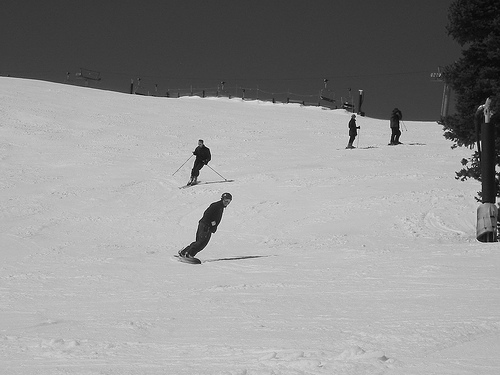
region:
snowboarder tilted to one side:
[161, 190, 244, 272]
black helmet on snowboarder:
[218, 186, 236, 207]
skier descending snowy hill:
[153, 131, 244, 196]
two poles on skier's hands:
[166, 151, 233, 183]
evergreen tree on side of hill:
[438, 94, 498, 202]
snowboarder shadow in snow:
[220, 245, 273, 265]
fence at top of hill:
[193, 79, 288, 109]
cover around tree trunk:
[470, 199, 498, 251]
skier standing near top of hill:
[338, 109, 368, 155]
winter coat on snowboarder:
[192, 197, 229, 233]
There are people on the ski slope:
[48, 23, 467, 348]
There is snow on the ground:
[23, 53, 443, 370]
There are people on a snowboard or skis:
[51, 39, 437, 374]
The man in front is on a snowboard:
[53, 21, 467, 367]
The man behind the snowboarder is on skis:
[104, 45, 413, 365]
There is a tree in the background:
[63, 1, 497, 249]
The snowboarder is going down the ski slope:
[103, 179, 426, 351]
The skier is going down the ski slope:
[90, 98, 379, 314]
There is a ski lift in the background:
[48, 41, 451, 318]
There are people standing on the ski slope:
[302, 79, 426, 219]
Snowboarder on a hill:
[163, 178, 238, 278]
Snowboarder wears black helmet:
[167, 182, 237, 268]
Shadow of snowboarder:
[208, 243, 286, 273]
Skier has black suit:
[166, 131, 241, 188]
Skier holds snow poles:
[166, 132, 236, 185]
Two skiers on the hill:
[326, 96, 416, 158]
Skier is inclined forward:
[173, 183, 245, 276]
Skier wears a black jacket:
[172, 175, 239, 281]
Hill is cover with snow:
[3, 70, 495, 371]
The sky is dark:
[1, 4, 439, 97]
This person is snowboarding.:
[155, 187, 257, 276]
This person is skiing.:
[163, 131, 230, 187]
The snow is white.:
[32, 289, 98, 328]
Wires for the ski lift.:
[360, 62, 432, 98]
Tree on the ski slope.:
[457, 77, 494, 109]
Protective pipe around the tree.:
[451, 208, 499, 234]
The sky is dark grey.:
[258, 23, 360, 57]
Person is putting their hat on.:
[371, 100, 426, 137]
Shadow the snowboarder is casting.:
[202, 251, 268, 275]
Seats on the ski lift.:
[297, 91, 367, 116]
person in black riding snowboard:
[175, 190, 231, 263]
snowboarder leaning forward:
[175, 190, 232, 265]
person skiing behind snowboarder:
[183, 138, 213, 183]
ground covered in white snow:
[2, 74, 498, 372]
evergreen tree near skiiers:
[434, 0, 497, 213]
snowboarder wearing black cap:
[218, 190, 233, 200]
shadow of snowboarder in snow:
[206, 252, 266, 262]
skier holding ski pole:
[203, 162, 228, 181]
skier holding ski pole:
[171, 155, 191, 175]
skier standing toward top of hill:
[346, 112, 360, 149]